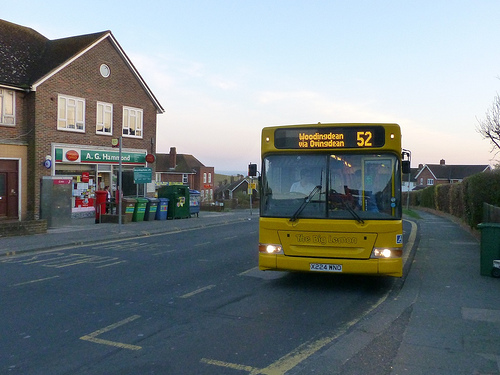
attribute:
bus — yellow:
[262, 119, 405, 280]